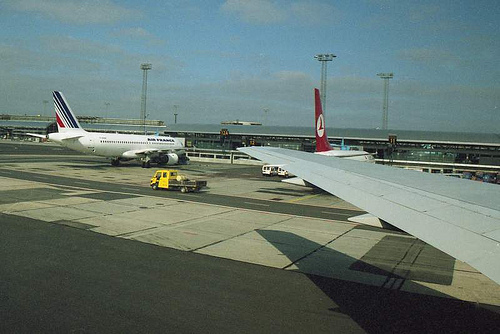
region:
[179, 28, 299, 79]
this is the sky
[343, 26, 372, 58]
the sky is blue in color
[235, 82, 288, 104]
this is the clouds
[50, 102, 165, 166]
this is a jet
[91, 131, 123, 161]
the jet is white in color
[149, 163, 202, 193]
this is a lorry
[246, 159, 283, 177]
this is a bus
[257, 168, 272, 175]
the bus is white in color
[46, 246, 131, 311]
this is a runaway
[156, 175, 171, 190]
the lorry is yellow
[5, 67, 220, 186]
the plane is white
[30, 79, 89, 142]
the tail is red, white, and blue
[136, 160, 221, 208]
a little yellow work truck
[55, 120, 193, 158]
passengers are on the plane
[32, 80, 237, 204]
the plane is parked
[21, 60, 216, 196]
the plane is at the airport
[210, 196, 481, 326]
shadow of a wing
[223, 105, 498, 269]
the wing of the plane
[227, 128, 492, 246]
the wing is light grey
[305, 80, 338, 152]
the wing of the plane is red and white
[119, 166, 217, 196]
a yellow towtruck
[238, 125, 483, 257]
a wing of the aeroplane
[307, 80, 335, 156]
a red wing of a plane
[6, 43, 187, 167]
a white parked plane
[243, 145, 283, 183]
two white cars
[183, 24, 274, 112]
the sky is dark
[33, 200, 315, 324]
the airports runway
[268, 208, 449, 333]
shadow of the wing of the plane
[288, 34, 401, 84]
watchtowers of the airport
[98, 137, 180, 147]
windows of the aircraft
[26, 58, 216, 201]
airplane at the airport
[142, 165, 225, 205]
luggage truck on the airport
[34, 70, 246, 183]
airplane on the airline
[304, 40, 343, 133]
tower on the top of airport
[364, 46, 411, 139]
tower on an airport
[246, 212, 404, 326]
airplane shadow on the ground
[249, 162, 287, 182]
white vans parked at the airport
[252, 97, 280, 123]
airplane tower off in distance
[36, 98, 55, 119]
airplane tower off in distance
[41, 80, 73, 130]
red and blue stripes on airplane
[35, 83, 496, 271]
two airplanes sitting at the airport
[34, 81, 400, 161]
two airplanes sitting at the airport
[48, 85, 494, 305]
three airplanes sitting at the airport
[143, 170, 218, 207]
yellow luggage truck parked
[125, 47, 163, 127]
airplane towers on the roof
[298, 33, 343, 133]
airplane towers on the roof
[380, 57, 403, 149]
airplane towers on the roof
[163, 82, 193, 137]
airplane towers on the roof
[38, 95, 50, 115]
airplane towers on the roof